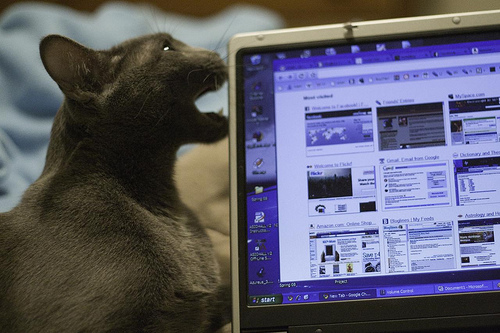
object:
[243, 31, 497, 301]
screen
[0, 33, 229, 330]
cat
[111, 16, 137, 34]
fabric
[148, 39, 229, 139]
face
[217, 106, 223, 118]
tooth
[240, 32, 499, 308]
monitor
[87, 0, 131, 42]
blanket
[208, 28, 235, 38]
whisker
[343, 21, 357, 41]
latch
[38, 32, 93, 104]
ear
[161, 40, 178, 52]
eye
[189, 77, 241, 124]
mouth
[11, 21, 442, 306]
nobody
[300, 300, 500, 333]
keyboard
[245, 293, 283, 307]
bar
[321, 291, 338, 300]
google chrome icon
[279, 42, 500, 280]
page